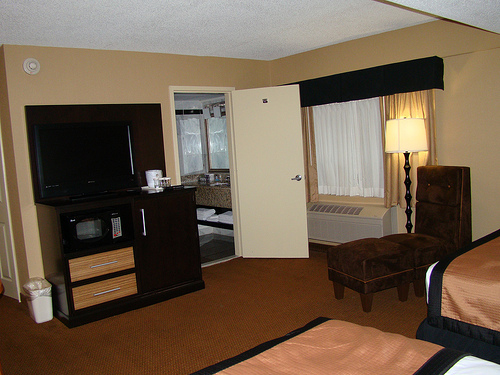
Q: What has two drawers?
A: The cabinet.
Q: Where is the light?
A: In the room.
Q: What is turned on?
A: The light.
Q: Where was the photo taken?
A: A room.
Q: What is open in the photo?
A: Door.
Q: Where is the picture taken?
A: A hotel room.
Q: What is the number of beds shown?
A: Two.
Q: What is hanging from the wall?
A: A television.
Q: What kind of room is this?
A: Bedroom.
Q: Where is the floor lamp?
A: In front of the curtains to the right.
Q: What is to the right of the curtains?
A: Brown chair.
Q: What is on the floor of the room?
A: Rug.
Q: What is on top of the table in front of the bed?
A: Television.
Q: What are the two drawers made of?
A: Wood.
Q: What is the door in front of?
A: Grey heater on the wall.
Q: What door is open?
A: Door next to heater.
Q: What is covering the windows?
A: Curtain panels.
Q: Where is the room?
A: Hotel.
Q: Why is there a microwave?
A: Prepare food.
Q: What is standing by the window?
A: Lamp.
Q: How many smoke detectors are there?
A: One.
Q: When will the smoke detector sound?
A: Fire.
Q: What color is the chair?
A: Brown.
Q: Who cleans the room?
A: Maid.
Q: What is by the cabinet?
A: Garbage can.